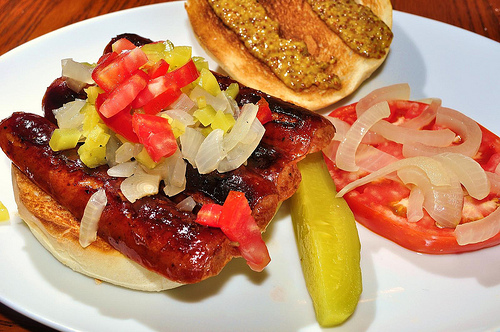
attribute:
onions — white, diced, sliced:
[354, 85, 490, 215]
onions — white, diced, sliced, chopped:
[175, 98, 263, 175]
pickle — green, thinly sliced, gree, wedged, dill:
[292, 147, 367, 331]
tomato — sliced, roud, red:
[307, 88, 497, 250]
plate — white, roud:
[7, 8, 498, 329]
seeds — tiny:
[313, 207, 342, 265]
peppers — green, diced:
[70, 86, 107, 168]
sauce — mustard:
[210, 0, 394, 90]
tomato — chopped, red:
[93, 38, 191, 156]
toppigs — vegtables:
[88, 36, 498, 314]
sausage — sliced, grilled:
[10, 29, 334, 307]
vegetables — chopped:
[60, 41, 272, 216]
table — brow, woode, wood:
[3, 1, 71, 27]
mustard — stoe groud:
[227, 5, 269, 41]